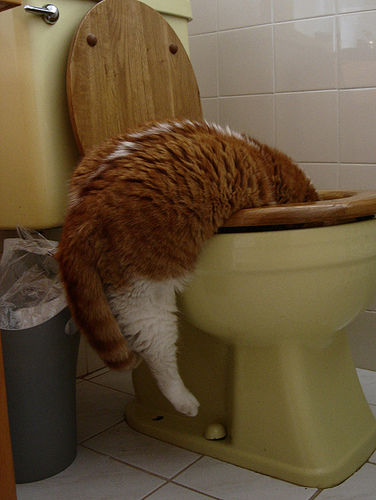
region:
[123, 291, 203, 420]
White leg of drinking cat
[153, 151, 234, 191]
Back of thirsty orange cat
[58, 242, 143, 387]
Striped tail of thirsty cat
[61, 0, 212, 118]
Open wooden toilet lid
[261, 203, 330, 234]
Part of wooden toilet seat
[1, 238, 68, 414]
Part of bathroom trash can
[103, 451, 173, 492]
Part of bathroom tile floor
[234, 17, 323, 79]
Part of white tile wall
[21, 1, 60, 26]
Toilet tank flush lever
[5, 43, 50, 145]
Side of toilet tank reservoir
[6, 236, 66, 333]
plastic bag in the trash can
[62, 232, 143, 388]
brown striped tail of the cat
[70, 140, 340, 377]
cat with it's head in the toilet bowl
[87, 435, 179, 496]
white tile floor of the bathroom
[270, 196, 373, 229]
wooden toilet seat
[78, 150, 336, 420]
brown and white cat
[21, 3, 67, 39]
silver handle on the toilet bowl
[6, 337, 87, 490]
grey trash can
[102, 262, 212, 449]
white leg hanging down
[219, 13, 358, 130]
white tiled wall in bathroom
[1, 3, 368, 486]
a yellow toilet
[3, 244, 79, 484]
a gray trash can with a plastic bag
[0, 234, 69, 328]
plastic trash bag in can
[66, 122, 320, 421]
orange and white cat in a toilet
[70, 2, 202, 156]
wood toilet seat cover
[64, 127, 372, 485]
yellow toilet bowl with a cat inside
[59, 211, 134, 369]
the cat's tail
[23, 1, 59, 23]
the toilet's metal handle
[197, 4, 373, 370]
an off-white tile wall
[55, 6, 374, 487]
A cat in a toilet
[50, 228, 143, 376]
Tail of a cat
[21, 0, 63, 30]
A silver toilet flusher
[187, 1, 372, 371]
Tiles on the wall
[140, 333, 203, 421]
White leg of the cat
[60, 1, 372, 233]
A brown wooden toilet seat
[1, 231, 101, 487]
Trash bin on the floor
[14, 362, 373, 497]
White tiles on the floor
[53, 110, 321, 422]
A brown and white cat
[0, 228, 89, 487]
Plastic bag in trash bin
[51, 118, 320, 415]
Orange and white cat climbing in toilet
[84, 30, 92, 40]
Stopper on toilet seat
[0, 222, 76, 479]
Grey garbage can in bathroom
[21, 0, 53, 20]
Silver handle on back of toilet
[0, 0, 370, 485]
Yellow toilet sitting on white tile floor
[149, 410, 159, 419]
Dark spot on side of toilet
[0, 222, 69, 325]
Plastic liner inside of toilet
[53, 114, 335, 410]
Cat with head hanging inside toilet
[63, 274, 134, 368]
Orange stripes on cat's tail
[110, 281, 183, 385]
Ruffled white fur on cat's leg